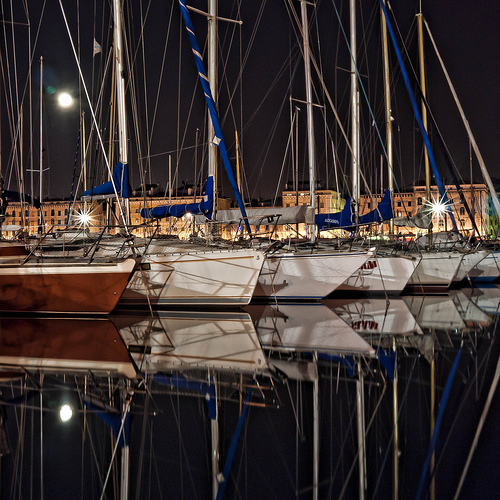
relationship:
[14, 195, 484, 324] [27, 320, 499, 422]
boats has reflections